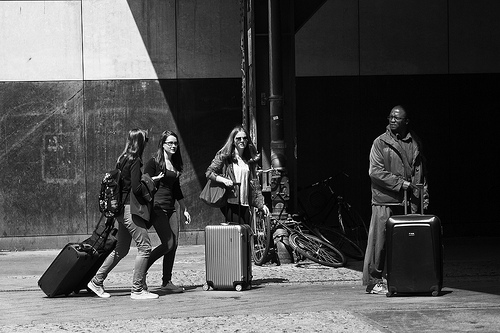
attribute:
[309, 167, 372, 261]
bike — leaning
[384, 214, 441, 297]
luggage — recatangular, black, tall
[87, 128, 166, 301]
woman — white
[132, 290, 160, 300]
shoe — white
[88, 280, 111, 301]
shoe — white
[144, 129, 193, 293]
person — white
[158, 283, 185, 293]
shoe — white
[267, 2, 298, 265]
pole — black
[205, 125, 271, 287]
person — white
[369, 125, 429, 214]
jacket — dark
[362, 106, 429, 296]
person — black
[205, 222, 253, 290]
luggage — rectangle, metallic, gray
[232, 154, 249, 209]
shirt — white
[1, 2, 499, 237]
wall — in background, white, black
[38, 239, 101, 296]
luggage — black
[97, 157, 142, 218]
bag — black